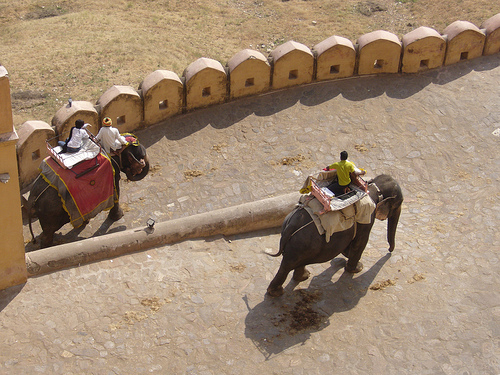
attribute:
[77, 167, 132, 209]
blanket — red, white, laid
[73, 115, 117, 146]
people — riding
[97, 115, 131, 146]
person — leading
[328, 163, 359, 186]
shirt — yellow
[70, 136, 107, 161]
shirt — white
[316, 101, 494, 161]
ground — here, sandy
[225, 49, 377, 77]
wall — concrete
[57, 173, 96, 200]
cloth — red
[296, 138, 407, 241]
man — riding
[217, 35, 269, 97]
pillsa — concrete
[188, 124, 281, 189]
dirt — tan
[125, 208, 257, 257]
post — wooden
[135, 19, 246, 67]
grass —  yellow ,  outside 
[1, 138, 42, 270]
pole — yellow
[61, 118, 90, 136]
boy — young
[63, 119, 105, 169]
child — young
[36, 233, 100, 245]
shadow — here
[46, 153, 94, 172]
basket — wire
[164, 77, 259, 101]
stones — holey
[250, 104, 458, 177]
walkway — dirt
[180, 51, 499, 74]
enclosure — concrete, here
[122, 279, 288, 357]
sand — brown, stony